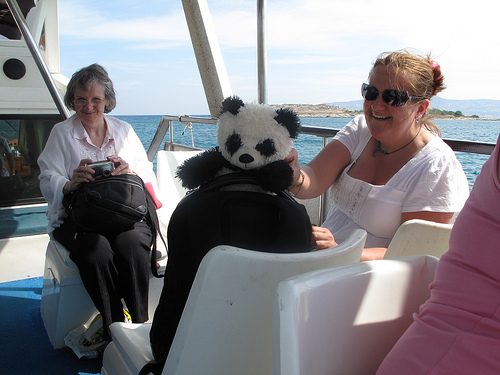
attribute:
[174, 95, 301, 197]
stuffed animal — panda, soft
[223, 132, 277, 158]
eyes — black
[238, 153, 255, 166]
nose — black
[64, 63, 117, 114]
hair — gray, grey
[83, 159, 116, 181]
camera — silver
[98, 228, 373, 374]
chair — white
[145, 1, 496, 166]
rail — white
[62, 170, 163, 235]
bag — black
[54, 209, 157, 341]
pants — black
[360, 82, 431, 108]
sunglasses — black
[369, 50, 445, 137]
hair — brown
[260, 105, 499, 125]
mountain — small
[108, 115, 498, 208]
body of water — large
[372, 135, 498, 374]
shirt — pink